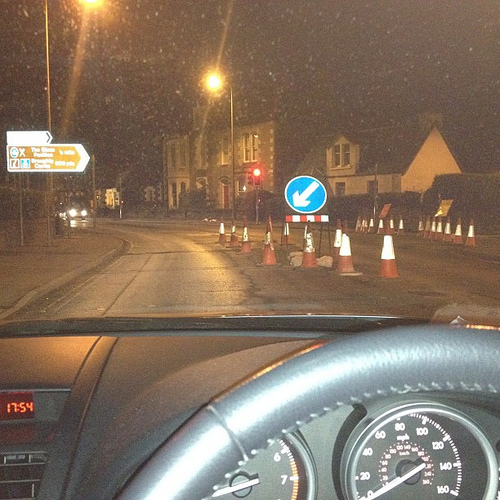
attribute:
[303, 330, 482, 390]
steering  wheel — gray, black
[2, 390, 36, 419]
clock — digital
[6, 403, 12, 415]
number — red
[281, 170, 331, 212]
sign — blue, round, green, circular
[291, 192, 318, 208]
arrow — white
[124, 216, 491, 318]
street — gray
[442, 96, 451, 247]
cone — orange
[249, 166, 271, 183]
traffic light — red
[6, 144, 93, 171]
sign — yellow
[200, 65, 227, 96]
streetlight — on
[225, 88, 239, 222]
pole — straight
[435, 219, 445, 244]
cone — orange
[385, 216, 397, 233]
cone — orange